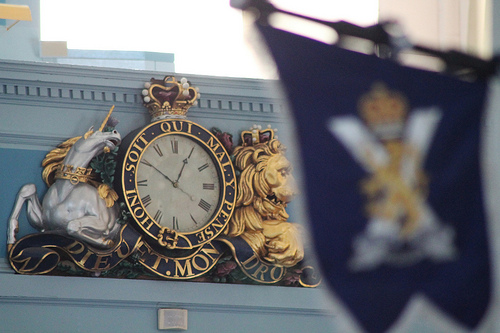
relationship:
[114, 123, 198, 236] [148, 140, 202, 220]
frame of clock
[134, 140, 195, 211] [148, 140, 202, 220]
face of clock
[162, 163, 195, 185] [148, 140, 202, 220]
hands of clock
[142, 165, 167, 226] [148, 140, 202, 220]
number on clock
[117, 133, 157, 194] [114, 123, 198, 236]
writing on frame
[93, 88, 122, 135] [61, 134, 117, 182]
horn of unicorn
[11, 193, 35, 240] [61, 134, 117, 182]
leg of unicorn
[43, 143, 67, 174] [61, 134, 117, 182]
man of unicorn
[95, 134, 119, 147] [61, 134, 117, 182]
nose of unicorn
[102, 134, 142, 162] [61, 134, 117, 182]
mouth of unicorn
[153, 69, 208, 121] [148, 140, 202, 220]
crowns on clock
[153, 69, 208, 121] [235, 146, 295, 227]
crowns on lion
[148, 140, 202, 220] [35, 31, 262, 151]
clock on buildings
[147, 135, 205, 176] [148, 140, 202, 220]
numeral on clock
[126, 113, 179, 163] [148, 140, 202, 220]
roman on clock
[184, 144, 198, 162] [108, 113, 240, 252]
numeral on clock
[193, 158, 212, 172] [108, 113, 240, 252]
numeral on clock